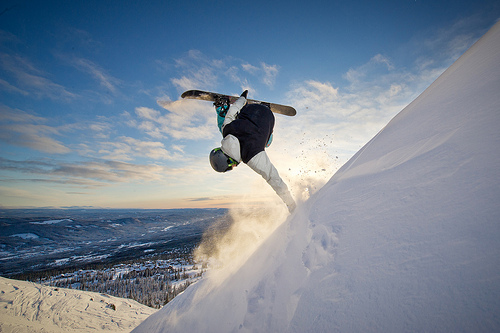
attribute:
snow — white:
[127, 17, 497, 330]